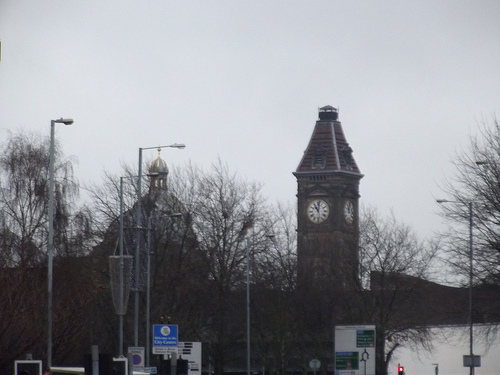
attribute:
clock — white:
[307, 199, 331, 224]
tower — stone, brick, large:
[292, 103, 364, 284]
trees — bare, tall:
[0, 112, 499, 373]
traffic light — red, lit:
[396, 362, 405, 374]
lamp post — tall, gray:
[436, 198, 475, 373]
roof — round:
[318, 102, 339, 120]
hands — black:
[314, 200, 322, 214]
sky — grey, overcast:
[0, 0, 499, 372]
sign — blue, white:
[151, 323, 180, 355]